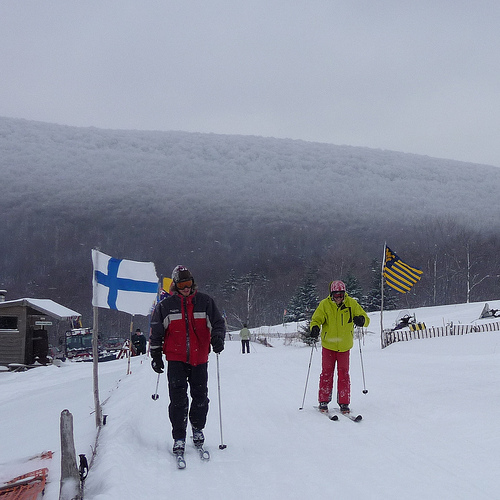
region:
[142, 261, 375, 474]
Two people are skiing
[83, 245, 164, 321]
A white and blue flag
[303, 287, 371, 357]
A bright yellow jacket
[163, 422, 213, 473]
A pair of skis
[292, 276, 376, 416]
Skiier holding two ski poles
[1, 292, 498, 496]
White snow on a hill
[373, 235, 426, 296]
Yellow and blue flag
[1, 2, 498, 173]
The sky is overcast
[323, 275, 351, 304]
Helmet on person's head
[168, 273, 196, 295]
A pair of goggles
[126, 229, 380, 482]
Two people on a ski slope.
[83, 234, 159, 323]
A blue and white flag.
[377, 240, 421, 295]
A yellow striped flag.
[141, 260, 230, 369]
Person wearing a red and grey jacket.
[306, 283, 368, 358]
Person wearing a yellow jacket.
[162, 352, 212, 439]
A pair of dark pants.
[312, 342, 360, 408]
A pair of red pants.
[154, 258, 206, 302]
Man on left wearing ski goggles.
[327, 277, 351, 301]
Man on rigtht wearing ski goggles.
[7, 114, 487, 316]
Mountain in the background.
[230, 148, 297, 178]
snow on the trees.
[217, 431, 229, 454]
ski pole in the snow.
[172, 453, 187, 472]
ski on man's foot.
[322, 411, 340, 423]
ski on woman's foot.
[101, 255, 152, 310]
white flag on pole.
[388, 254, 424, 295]
yellow flag on pole.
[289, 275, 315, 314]
pine tree with snow on it.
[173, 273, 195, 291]
goggles on man's face.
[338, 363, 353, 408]
red pants on woman.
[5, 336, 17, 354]
siding on the building.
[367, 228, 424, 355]
the American Flag on a pole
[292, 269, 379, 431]
man wears skis on the snow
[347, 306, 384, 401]
a pole on left hand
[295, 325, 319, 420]
a pole on right hand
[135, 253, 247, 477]
man wears a snow coat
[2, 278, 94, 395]
a building on the hill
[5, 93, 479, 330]
a mountain on the background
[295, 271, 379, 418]
man wears red pants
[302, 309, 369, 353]
black gloves on hands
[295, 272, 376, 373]
man wears a green coat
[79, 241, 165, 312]
the blue and white flag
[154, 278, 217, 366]
the red and black jacket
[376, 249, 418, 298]
the blue and yellow stripped flag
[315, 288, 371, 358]
the yellow jacket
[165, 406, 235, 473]
the man's snow skis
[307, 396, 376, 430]
the womans snow skis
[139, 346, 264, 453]
the man's ski poles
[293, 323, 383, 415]
the womans ski poles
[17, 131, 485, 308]
the mountain behind them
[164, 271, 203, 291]
the man's goggles